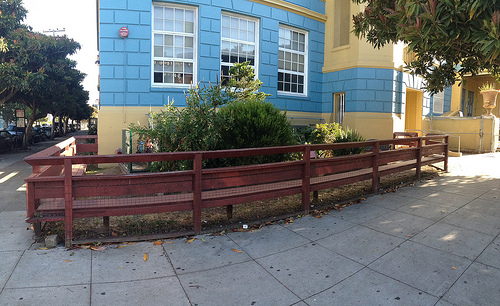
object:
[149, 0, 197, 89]
window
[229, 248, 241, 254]
leaves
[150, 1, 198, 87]
frame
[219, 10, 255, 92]
window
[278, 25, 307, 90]
window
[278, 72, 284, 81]
pane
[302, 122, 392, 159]
plant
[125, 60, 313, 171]
green foilage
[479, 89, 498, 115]
pot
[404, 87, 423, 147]
doorway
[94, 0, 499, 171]
building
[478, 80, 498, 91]
urn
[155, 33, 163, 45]
window pane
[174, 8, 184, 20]
window pane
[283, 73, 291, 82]
window pane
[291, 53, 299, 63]
window pane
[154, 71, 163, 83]
window pane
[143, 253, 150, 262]
leaf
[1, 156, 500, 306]
sidewalk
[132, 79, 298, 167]
shrubber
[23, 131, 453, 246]
fence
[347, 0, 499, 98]
green trees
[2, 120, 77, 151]
cars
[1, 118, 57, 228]
street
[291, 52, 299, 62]
window pane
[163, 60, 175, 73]
pane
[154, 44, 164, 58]
pane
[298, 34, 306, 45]
pane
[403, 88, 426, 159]
way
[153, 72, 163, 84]
pane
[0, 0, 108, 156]
rees.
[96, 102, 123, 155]
paint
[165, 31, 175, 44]
pane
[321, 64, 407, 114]
stripe